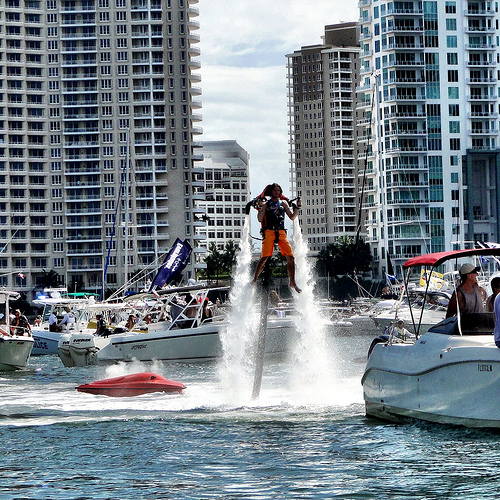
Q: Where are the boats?
A: In water.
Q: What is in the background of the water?
A: Buildings.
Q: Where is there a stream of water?
A: Behind person jumping.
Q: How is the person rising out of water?
A: Engine on backpack.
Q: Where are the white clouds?
A: In sky.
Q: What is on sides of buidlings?
A: Balconies.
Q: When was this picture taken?
A: Daytime.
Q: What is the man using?
A: A water jetpack.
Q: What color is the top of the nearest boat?
A: Red.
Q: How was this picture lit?
A: Sunlight.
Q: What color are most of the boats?
A: White.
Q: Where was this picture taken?
A: In an urban waterway.